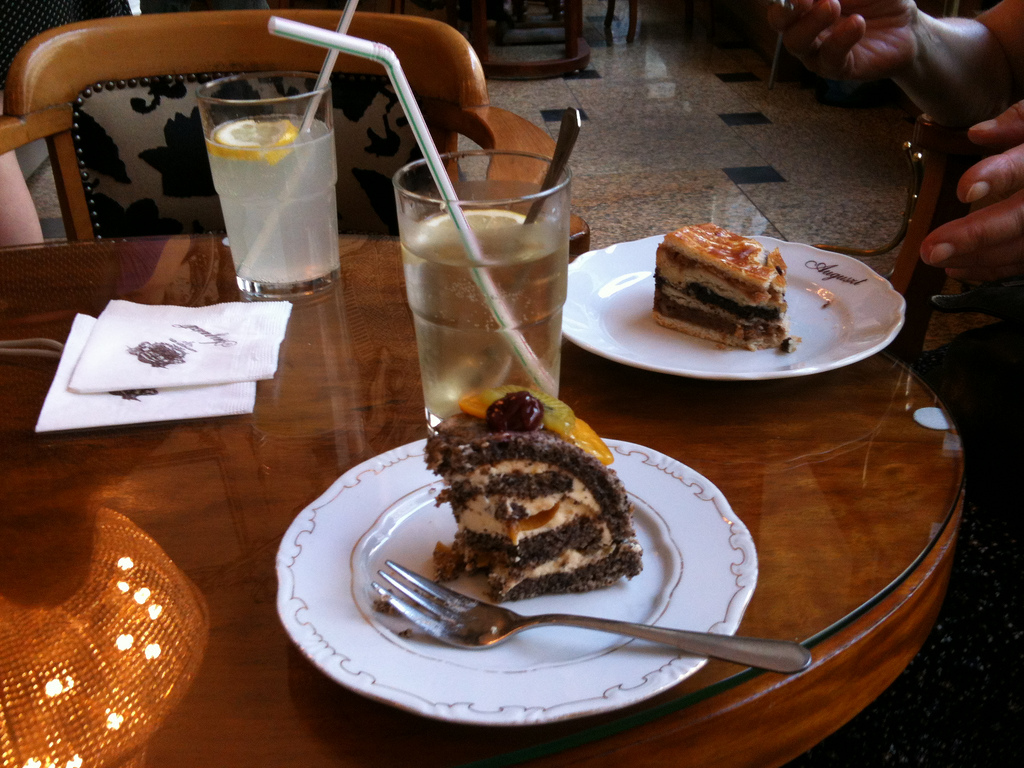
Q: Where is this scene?
A: In a restaurant.